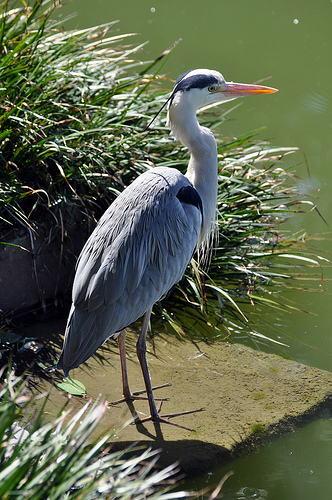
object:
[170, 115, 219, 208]
neck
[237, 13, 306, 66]
water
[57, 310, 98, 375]
tail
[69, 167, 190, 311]
feathers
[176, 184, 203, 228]
streak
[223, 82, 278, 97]
beak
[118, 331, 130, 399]
left leg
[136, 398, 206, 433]
talons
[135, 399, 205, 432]
feet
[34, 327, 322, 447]
concrete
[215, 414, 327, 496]
murkygreenwater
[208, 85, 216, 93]
eye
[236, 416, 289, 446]
edge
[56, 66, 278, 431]
bird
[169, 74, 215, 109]
streak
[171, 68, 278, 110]
head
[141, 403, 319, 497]
water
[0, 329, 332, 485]
shore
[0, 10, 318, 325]
bush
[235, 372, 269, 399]
ground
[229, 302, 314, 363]
water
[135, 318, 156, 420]
leg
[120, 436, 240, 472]
shadow